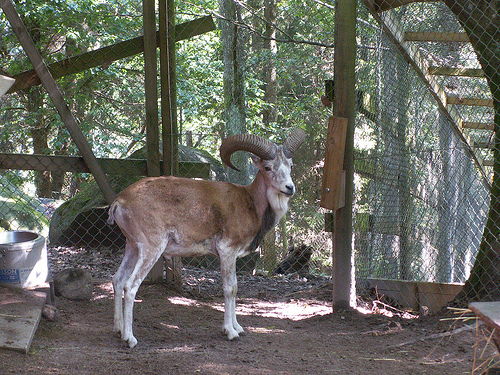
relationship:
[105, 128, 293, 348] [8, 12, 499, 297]
goat next to fence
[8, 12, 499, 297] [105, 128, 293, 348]
fence next to goat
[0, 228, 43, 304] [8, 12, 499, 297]
bucket next to fence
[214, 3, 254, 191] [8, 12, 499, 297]
tree other side of fence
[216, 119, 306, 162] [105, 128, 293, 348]
horns of goat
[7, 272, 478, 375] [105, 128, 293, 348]
dirt below goat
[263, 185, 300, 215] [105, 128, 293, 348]
chin of goat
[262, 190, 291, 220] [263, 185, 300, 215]
hair of chin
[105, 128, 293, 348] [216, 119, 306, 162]
goat has horns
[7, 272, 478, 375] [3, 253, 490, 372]
dirt on ground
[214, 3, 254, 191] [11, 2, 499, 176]
tree in background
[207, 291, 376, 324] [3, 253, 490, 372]
reflection on ground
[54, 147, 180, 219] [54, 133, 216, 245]
mold on rock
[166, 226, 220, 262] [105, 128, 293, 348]
stomach of goat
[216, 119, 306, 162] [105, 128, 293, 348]
horns on goat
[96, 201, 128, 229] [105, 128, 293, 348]
tail of goat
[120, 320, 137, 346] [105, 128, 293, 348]
hoof of goat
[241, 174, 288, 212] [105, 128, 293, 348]
neck of goat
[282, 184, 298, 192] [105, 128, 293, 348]
nose of goat